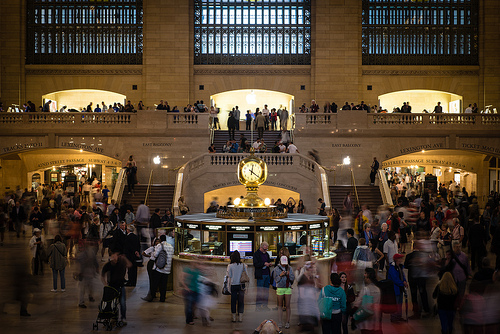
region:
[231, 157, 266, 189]
this is a clock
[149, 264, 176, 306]
these are black pants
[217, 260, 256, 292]
this is a white shirt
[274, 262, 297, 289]
this is a gray shirt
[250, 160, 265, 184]
these are clock hands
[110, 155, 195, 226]
this is a staircase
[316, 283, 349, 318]
this is a blue shirt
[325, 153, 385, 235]
this is a rail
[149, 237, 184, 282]
this is a white shirt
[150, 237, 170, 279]
this is a backpack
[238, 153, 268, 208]
white and gold clock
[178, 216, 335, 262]
ticket booth windows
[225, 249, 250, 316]
woman holding tan hand bag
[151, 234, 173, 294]
person holding grey back pack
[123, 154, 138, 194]
person walking on stairs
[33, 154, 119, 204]
hall way to subway trains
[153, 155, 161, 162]
light hanging on wall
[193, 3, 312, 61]
covered window on wall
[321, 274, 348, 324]
girl wearing blue sweat shirt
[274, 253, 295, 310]
person looking at cell phone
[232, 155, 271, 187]
The clock face is lite.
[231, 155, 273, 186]
The clock face is white.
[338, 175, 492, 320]
A lot of people are in the picture.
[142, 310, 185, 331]
The floor is brown.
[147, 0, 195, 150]
The walls are brown.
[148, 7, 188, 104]
The walls are made of stone blocks.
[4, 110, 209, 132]
The guard rails are made of stone.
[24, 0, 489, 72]
The windows are large.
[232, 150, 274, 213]
The clock is on a pedestal.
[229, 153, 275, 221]
The clock is gold.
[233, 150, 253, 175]
edge of a clock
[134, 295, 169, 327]
part of a floor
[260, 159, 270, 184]
edge of a clock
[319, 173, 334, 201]
part of a handle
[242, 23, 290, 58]
part of a window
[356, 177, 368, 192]
part of a stair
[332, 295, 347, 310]
part of a jumper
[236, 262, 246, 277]
edge of a bag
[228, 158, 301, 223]
a clock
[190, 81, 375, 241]
a clock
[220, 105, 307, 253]
a clock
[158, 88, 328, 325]
a clock